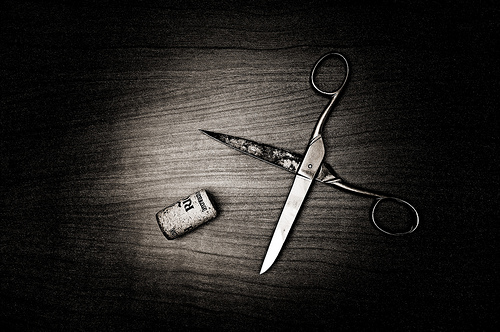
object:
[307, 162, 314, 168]
screw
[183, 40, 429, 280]
scissors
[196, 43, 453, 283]
scissors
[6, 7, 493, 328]
wooden surface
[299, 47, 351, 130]
handle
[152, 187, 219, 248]
cork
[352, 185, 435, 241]
left handle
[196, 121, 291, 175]
blade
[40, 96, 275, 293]
wood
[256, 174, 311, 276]
blade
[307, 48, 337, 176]
handle